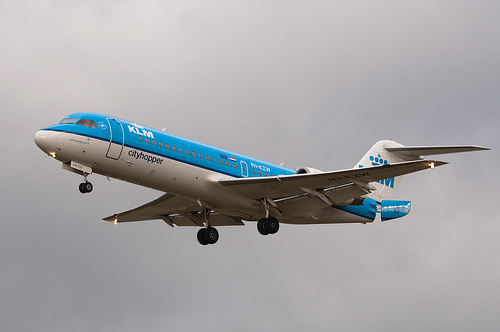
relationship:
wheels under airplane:
[79, 182, 280, 246] [34, 112, 492, 245]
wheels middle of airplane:
[198, 216, 279, 244] [34, 112, 492, 245]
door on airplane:
[105, 117, 125, 160] [34, 112, 492, 245]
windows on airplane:
[138, 135, 275, 180] [34, 112, 492, 245]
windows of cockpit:
[57, 118, 98, 129] [56, 118, 97, 130]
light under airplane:
[48, 152, 59, 158] [34, 112, 492, 245]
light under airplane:
[112, 217, 120, 225] [34, 112, 492, 245]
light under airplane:
[428, 161, 435, 169] [34, 112, 492, 245]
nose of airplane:
[34, 123, 66, 154] [34, 112, 492, 245]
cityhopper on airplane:
[126, 149, 165, 165] [34, 112, 492, 245]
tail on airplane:
[349, 138, 423, 203] [34, 112, 492, 245]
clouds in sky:
[0, 1, 499, 331] [0, 0, 499, 331]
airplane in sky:
[34, 112, 492, 245] [0, 0, 499, 331]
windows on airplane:
[57, 118, 98, 129] [34, 112, 492, 245]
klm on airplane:
[128, 126, 155, 140] [34, 112, 492, 245]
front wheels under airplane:
[77, 181, 93, 193] [34, 112, 492, 245]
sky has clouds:
[0, 0, 499, 331] [0, 1, 499, 331]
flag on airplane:
[229, 154, 237, 164] [34, 112, 492, 245]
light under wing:
[112, 217, 120, 225] [101, 191, 244, 227]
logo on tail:
[358, 153, 397, 189] [349, 138, 423, 203]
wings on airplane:
[102, 159, 450, 227] [34, 112, 492, 245]